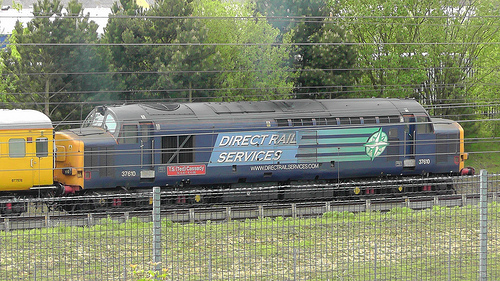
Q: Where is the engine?
A: On train.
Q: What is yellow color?
A: Train car.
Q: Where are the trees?
A: Forest.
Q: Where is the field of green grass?
A: Beside the tracks.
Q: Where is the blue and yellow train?
A: On the tracks.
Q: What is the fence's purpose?
A: To fence in the area.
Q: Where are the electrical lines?
A: In the air.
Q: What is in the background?
A: Trees.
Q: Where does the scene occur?
A: Outdoors near a railroad track.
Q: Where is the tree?
A: Behind the train.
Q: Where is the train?
A: On the railroad tracks.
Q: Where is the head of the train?
A: In front.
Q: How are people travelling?
A: By train.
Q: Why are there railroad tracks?
A: So train can run.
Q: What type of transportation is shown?
A: Train.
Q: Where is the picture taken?
A: Near railroad tracks.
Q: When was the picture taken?
A: During the daytime.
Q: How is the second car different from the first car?
A: It is yellow.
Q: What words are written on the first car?
A: Direct Rail Services.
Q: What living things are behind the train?
A: Trees.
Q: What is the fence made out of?
A: Wire.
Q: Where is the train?
A: On the track.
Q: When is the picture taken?
A: Daytime.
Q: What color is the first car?
A: Blue.